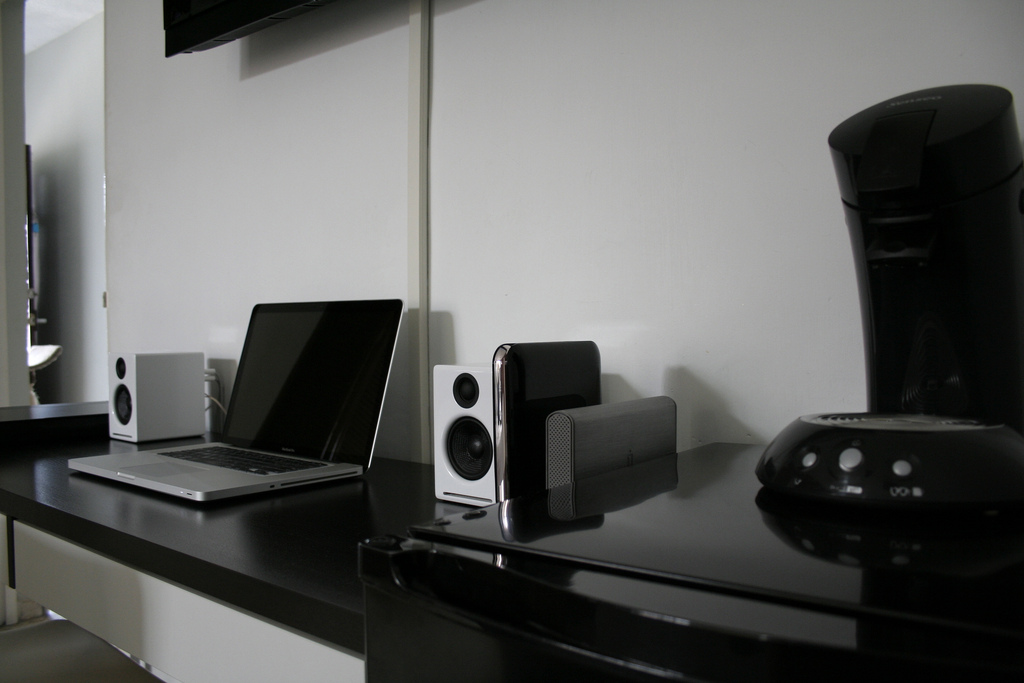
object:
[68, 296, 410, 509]
laptop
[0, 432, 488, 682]
desk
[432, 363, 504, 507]
speaker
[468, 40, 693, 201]
wall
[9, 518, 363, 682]
drawer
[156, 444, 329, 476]
keyboard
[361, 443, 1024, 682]
fridge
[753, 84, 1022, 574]
coffee maker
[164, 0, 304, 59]
tv